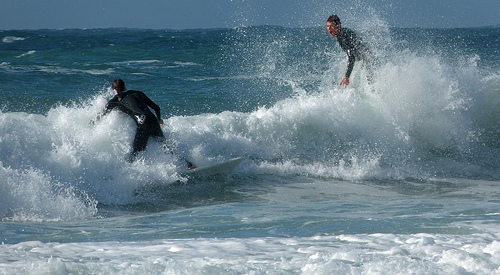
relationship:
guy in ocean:
[92, 75, 196, 167] [2, 26, 497, 273]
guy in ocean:
[320, 13, 383, 91] [2, 26, 497, 273]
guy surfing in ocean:
[320, 13, 383, 91] [2, 26, 497, 273]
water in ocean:
[286, 236, 392, 268] [42, 68, 437, 258]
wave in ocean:
[3, 52, 495, 232] [195, 7, 489, 240]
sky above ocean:
[1, 1, 498, 28] [2, 26, 497, 273]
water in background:
[2, 30, 496, 270] [4, 84, 498, 214]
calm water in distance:
[6, 26, 217, 71] [12, 67, 492, 137]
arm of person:
[336, 42, 358, 85] [323, 14, 382, 93]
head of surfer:
[315, 54, 342, 75] [90, 72, 196, 172]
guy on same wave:
[320, 13, 383, 91] [3, 52, 495, 232]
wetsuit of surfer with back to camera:
[112, 77, 171, 169] [92, 101, 223, 258]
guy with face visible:
[320, 13, 383, 91] [322, 49, 342, 82]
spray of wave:
[2, 0, 499, 221] [66, 50, 423, 180]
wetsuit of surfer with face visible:
[313, 13, 412, 83] [278, 72, 392, 162]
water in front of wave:
[2, 30, 496, 270] [248, 88, 497, 192]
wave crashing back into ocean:
[3, 52, 495, 232] [4, 168, 498, 259]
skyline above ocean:
[48, 50, 132, 129] [2, 26, 497, 273]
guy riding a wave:
[92, 75, 196, 167] [227, 87, 479, 172]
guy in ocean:
[92, 75, 196, 167] [3, 160, 498, 274]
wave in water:
[3, 52, 495, 232] [2, 30, 496, 270]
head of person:
[324, 12, 341, 39] [324, 13, 377, 88]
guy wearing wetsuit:
[92, 75, 196, 167] [90, 89, 200, 175]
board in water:
[186, 153, 244, 178] [2, 30, 496, 270]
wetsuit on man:
[112, 77, 171, 169] [94, 71, 169, 159]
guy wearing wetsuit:
[92, 75, 196, 167] [109, 92, 187, 169]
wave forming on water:
[3, 52, 495, 232] [2, 30, 496, 270]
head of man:
[327, 12, 341, 37] [327, 13, 377, 88]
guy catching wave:
[92, 75, 196, 167] [3, 52, 495, 232]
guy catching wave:
[320, 13, 383, 91] [3, 52, 495, 232]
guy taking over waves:
[320, 13, 383, 91] [263, 57, 497, 174]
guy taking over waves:
[92, 75, 196, 167] [5, 109, 155, 210]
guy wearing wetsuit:
[92, 75, 196, 167] [117, 96, 170, 145]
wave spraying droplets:
[3, 52, 495, 232] [43, 145, 184, 190]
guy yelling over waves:
[320, 13, 383, 91] [275, 85, 479, 177]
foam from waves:
[1, 232, 497, 274] [2, 25, 497, 233]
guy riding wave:
[320, 13, 383, 91] [268, 82, 495, 169]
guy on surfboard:
[92, 75, 196, 167] [159, 152, 253, 182]